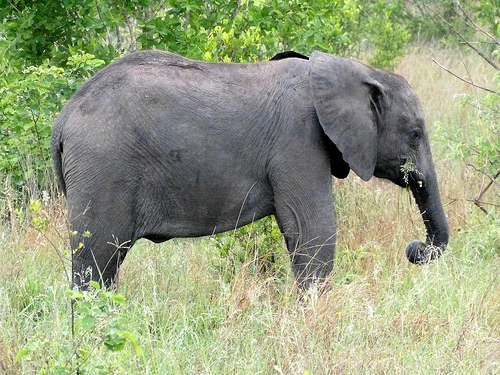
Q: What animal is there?
A: Elephant.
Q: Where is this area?
A: Grassland.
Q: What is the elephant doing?
A: Eating.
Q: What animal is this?
A: Elephant.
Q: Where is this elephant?
A: Field.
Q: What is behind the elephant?
A: Bushes.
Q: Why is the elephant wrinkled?
A: Dry Skin.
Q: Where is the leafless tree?
A: Right.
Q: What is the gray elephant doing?
A: Grazing.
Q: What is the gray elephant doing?
A: Eating grass.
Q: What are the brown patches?
A: Dead grass.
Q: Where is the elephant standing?
A: On grass.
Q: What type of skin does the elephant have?
A: Rough skin.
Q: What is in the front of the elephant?
A: A trunk.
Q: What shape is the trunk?
A: Curved.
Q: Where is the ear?
A: On the elephant's head.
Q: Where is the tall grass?
A: On the ground.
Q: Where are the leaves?
A: Behind the elephant.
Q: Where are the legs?
A: In the grass.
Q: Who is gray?
A: The elephant.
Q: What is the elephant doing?
A: Standing.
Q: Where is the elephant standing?
A: In grass.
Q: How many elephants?
A: One.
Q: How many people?
A: No people.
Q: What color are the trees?
A: Green.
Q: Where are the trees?
A: Behind the elephant.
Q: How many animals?
A: One.